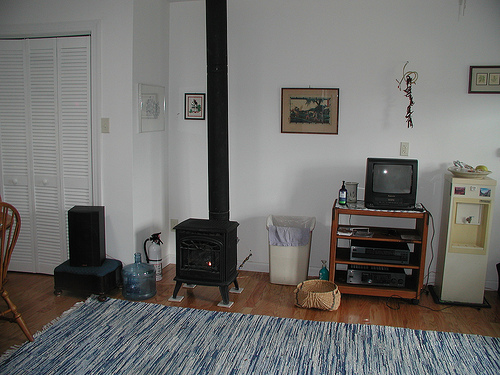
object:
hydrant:
[129, 225, 189, 286]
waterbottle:
[121, 247, 158, 297]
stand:
[328, 192, 433, 307]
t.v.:
[363, 155, 418, 210]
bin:
[262, 213, 319, 295]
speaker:
[58, 173, 125, 273]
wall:
[327, 33, 379, 84]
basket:
[280, 248, 356, 315]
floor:
[349, 293, 442, 330]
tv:
[363, 157, 422, 210]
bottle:
[335, 180, 351, 207]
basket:
[290, 279, 341, 312]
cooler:
[436, 125, 498, 342]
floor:
[0, 282, 55, 307]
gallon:
[117, 248, 161, 303]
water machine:
[436, 156, 494, 313]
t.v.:
[360, 146, 420, 214]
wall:
[229, 8, 493, 300]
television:
[361, 152, 426, 220]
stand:
[327, 202, 433, 308]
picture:
[269, 83, 346, 138]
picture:
[177, 85, 207, 124]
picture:
[459, 59, 497, 97]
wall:
[166, 10, 492, 288]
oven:
[168, 203, 245, 306]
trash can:
[271, 212, 319, 289]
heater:
[172, 0, 241, 305]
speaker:
[48, 200, 158, 292]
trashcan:
[266, 211, 316, 287]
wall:
[134, 5, 499, 292]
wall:
[90, 5, 497, 216]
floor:
[2, 238, 499, 373]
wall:
[292, 15, 386, 72]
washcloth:
[267, 223, 312, 249]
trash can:
[264, 212, 315, 285]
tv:
[359, 151, 424, 211]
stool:
[323, 193, 434, 303]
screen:
[372, 163, 413, 193]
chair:
[0, 197, 36, 347]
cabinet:
[331, 197, 431, 304]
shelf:
[335, 197, 425, 217]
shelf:
[336, 223, 421, 243]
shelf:
[335, 247, 420, 269]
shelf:
[332, 270, 417, 292]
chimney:
[153, 16, 262, 297]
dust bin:
[265, 214, 317, 286]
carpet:
[2, 289, 495, 370]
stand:
[329, 193, 428, 301]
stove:
[166, 213, 241, 305]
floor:
[4, 268, 497, 372]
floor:
[2, 264, 483, 363]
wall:
[259, 11, 380, 77]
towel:
[265, 223, 313, 245]